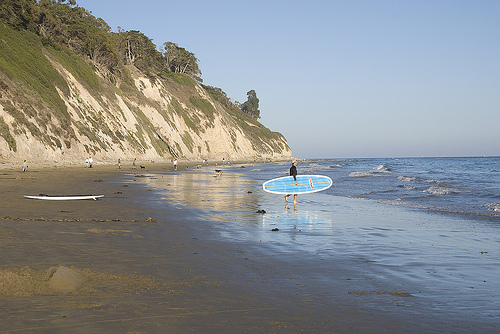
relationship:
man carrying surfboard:
[284, 160, 301, 205] [257, 172, 334, 197]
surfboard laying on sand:
[19, 190, 105, 202] [32, 201, 102, 215]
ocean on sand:
[227, 157, 499, 227] [0, 155, 497, 332]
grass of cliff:
[3, 15, 172, 155] [3, 10, 298, 166]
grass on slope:
[10, 9, 306, 197] [214, 103, 290, 160]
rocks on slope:
[78, 123, 200, 155] [214, 103, 290, 160]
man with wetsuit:
[284, 160, 301, 205] [287, 167, 299, 180]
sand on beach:
[6, 259, 123, 301] [129, 198, 307, 305]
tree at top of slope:
[64, 18, 134, 54] [200, 83, 290, 157]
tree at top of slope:
[166, 46, 200, 79] [200, 83, 290, 157]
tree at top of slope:
[37, 3, 85, 43] [200, 83, 290, 157]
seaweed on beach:
[334, 279, 430, 311] [338, 278, 410, 299]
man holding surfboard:
[284, 160, 301, 205] [256, 175, 338, 196]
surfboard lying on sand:
[19, 193, 105, 202] [6, 245, 123, 301]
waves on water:
[332, 154, 496, 219] [459, 170, 495, 220]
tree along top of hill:
[241, 87, 263, 117] [0, 11, 301, 166]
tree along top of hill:
[159, 42, 198, 77] [0, 11, 301, 166]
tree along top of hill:
[120, 30, 150, 67] [0, 11, 301, 166]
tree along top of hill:
[80, 22, 110, 69] [0, 11, 301, 166]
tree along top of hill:
[27, 4, 54, 36] [0, 11, 301, 166]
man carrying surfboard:
[284, 160, 301, 205] [251, 168, 337, 198]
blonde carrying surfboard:
[284, 159, 302, 210] [259, 172, 344, 194]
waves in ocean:
[363, 163, 442, 207] [227, 157, 499, 227]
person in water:
[426, 175, 440, 189] [382, 162, 491, 207]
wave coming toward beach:
[391, 179, 428, 191] [0, 167, 499, 332]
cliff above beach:
[3, 10, 298, 166] [9, 167, 494, 332]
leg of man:
[291, 192, 298, 211] [284, 160, 301, 205]